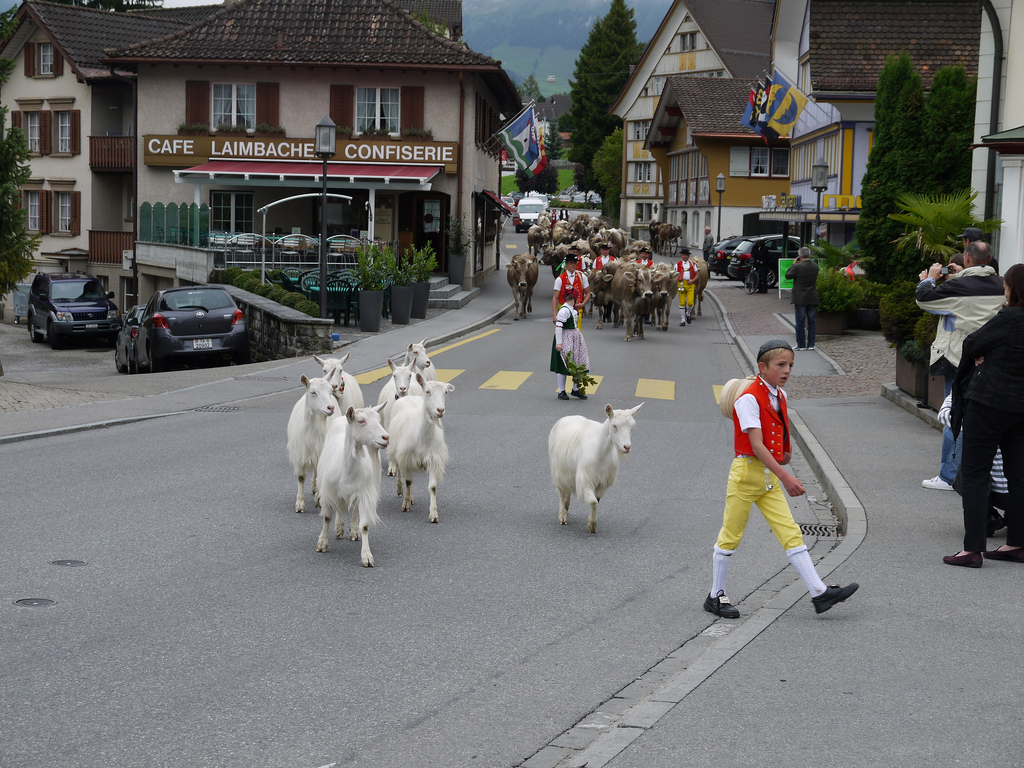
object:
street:
[106, 268, 954, 755]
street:
[365, 222, 857, 758]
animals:
[291, 364, 335, 507]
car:
[135, 282, 246, 371]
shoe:
[695, 592, 741, 612]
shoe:
[808, 577, 859, 614]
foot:
[703, 588, 742, 619]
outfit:
[702, 378, 855, 617]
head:
[339, 402, 393, 452]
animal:
[318, 401, 401, 564]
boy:
[699, 336, 860, 622]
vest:
[734, 382, 791, 462]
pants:
[718, 453, 818, 553]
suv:
[30, 269, 125, 347]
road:
[8, 323, 246, 408]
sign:
[147, 134, 465, 171]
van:
[514, 191, 547, 234]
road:
[503, 224, 706, 671]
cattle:
[500, 249, 546, 313]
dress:
[550, 306, 597, 377]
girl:
[553, 297, 597, 399]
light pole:
[310, 152, 337, 313]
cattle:
[615, 262, 653, 336]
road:
[76, 227, 834, 759]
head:
[603, 398, 642, 451]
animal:
[546, 401, 660, 527]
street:
[16, 281, 650, 755]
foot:
[805, 581, 857, 614]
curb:
[540, 627, 858, 764]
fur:
[551, 419, 590, 493]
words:
[184, 137, 201, 161]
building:
[106, 0, 518, 306]